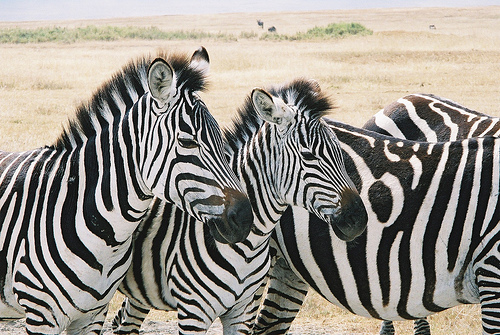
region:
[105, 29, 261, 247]
Side profile of a zebra's head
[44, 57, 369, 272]
Two zebras standing next to each other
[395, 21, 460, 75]
A patch of sandy ground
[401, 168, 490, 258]
Black and white stripes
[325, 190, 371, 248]
A black animal snout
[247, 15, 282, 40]
Two animals seen in the distance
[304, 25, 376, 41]
A length of low bushes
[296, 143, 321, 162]
A small black animal eye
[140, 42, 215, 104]
Two pointed animal ears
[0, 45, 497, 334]
Zebras standing in a row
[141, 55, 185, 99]
The ear of a zebra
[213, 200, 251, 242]
A zebra's black nose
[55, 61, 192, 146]
A white and black mane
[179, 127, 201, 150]
A zebra's black eye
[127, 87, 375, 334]
A small zebra in the line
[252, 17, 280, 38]
Animals behind the zebras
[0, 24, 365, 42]
Shrubs in the wild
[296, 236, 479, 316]
The belly of a zebra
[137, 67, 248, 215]
face of the zebra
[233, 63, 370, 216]
face of the another zebra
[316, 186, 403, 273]
mouth of the zebra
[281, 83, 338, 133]
black skin of zebra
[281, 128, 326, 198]
eyes of the zebra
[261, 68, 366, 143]
top part of the zebra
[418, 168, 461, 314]
white skin of zebra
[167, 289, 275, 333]
legs of the zebra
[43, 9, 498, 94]
a clear view of sand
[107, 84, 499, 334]
Zebras standing side by side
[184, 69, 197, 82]
Mane on zebra head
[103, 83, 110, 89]
Black hair on the mane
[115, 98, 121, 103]
White stripe on the mane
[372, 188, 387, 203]
An black spot in the center of white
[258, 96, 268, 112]
Inside of the zebra ear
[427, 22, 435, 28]
A lone animal in the background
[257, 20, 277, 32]
Two dark animals in the background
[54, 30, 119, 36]
Vegetation in the background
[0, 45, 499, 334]
a small pack of zebra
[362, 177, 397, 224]
a black circular mark on the zebra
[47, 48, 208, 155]
striped hair in the zebra's mane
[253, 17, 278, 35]
a few animals in the distance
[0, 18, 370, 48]
small bushes in the middle of the dry field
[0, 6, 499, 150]
a field covered in dried grass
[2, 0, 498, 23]
a hazy overcast sky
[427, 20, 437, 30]
an animal grazing in the distance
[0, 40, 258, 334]
a zebra standing in a group of four zebras